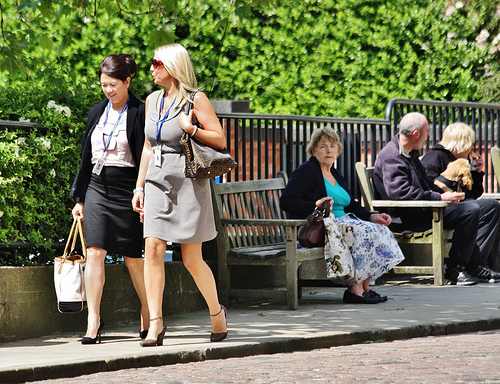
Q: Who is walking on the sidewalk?
A: Two women.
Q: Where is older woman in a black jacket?
A: Sitting on the first bench.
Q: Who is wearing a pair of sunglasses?
A: Young woman with blonde hair.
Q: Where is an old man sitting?
A: On bench on the far right.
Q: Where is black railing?
A: Behind the benches.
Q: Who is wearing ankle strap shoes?
A: Young woman with blonde hair.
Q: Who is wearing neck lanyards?
A: Two women on the sidewalk.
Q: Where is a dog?
A: On bench between two people.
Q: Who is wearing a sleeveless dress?
A: Young woman with blonde hair.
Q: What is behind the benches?
A: Black fence.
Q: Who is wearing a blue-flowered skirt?
A: A woman.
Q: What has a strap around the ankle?
A: A shoe.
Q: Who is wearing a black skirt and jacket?
A: A lady.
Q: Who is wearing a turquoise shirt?
A: A woman.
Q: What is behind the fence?
A: Brick wall.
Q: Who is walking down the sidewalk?
A: Two women.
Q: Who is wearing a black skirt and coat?
A: A woman.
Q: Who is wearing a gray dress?
A: The blonde woman.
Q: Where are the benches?
A: On the sidewalk.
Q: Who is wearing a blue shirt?
A: The woman on the bench.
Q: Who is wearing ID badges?
A: The two walking women.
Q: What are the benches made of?
A: Wood.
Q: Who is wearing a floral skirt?
A: The woman on the bench.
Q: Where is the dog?
A: Between the couple on the bench.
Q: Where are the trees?
A: Behind the black fence.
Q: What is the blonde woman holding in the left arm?
A: A purse.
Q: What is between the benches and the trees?
A: A metal fence.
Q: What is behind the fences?
A: Green trees.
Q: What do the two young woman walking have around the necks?
A: Lanyards.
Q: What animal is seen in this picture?
A: A dog.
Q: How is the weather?
A: Sunny.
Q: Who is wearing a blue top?
A: Woman seated on the bench.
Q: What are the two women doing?
A: They are walking.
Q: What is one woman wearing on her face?
A: Sunglasses.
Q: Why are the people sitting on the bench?
A: Resting.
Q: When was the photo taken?
A: Day time.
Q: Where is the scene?
A: Outside a park.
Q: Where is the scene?
A: A sidewalk.